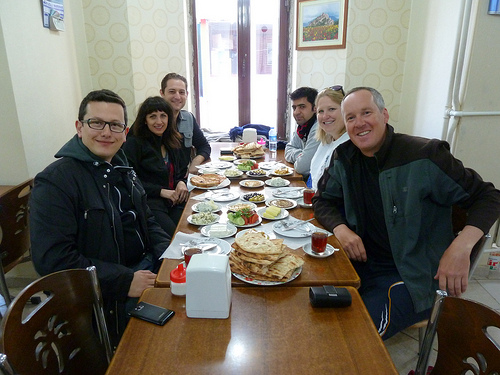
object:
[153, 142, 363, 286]
table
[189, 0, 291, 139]
frame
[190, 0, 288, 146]
door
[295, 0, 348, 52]
picture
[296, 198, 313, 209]
small plate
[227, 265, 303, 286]
plate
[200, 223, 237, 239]
plate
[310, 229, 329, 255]
glass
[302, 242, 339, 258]
saucer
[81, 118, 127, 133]
glasses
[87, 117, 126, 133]
rim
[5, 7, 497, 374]
room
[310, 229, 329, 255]
beverage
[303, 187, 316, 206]
glass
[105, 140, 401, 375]
dining table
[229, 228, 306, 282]
bread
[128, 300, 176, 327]
cell phone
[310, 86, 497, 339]
person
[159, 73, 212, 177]
person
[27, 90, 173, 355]
people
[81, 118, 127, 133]
black glasses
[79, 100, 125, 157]
face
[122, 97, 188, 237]
person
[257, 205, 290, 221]
round plate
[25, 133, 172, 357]
jacket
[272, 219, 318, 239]
plates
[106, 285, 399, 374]
table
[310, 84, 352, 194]
person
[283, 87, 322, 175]
person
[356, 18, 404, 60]
wall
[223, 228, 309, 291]
pita